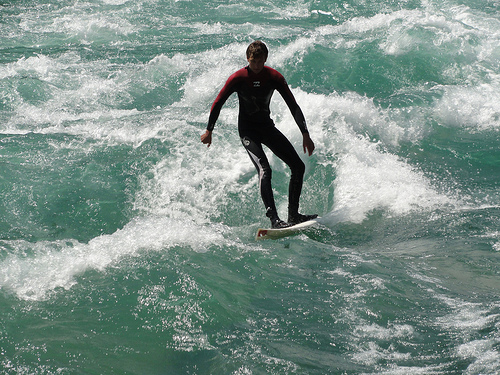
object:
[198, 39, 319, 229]
man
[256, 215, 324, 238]
surfboard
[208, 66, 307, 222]
wetsuit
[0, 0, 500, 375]
ocean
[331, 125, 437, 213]
wave cap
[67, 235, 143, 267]
sea foam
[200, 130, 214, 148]
hand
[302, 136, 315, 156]
hand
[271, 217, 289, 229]
foot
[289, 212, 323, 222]
foot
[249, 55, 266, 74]
face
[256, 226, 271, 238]
tip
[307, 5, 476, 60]
wave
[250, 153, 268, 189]
stripe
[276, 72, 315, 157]
arm